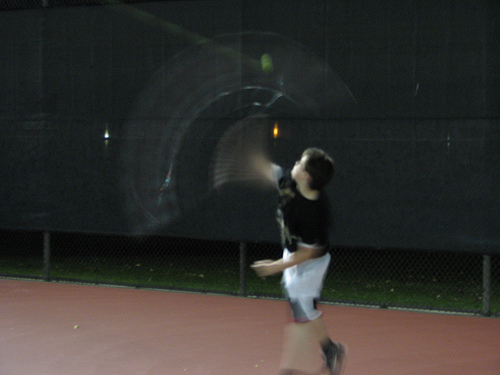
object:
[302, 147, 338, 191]
hair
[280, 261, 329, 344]
leg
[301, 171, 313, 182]
ear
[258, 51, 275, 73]
ball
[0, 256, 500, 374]
surface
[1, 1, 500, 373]
picture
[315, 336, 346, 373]
shoes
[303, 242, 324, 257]
elbow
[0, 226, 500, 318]
fence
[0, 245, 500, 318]
grass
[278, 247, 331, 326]
shorts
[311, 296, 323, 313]
design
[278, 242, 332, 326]
pants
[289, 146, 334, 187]
head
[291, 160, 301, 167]
nose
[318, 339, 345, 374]
foot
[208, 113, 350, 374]
boy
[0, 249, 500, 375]
court